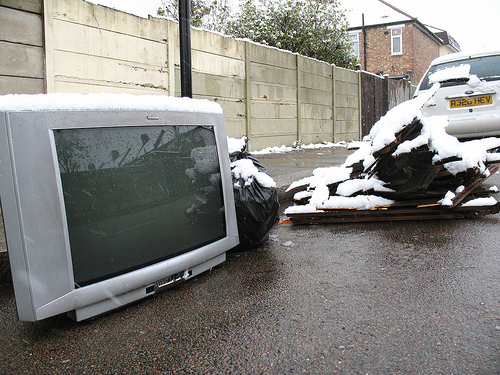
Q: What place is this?
A: It is a pavement.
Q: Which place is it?
A: It is a pavement.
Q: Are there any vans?
A: No, there are no vans.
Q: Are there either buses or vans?
A: No, there are no vans or buses.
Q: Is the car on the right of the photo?
A: Yes, the car is on the right of the image.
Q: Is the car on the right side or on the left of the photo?
A: The car is on the right of the image.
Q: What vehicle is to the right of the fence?
A: The vehicle is a car.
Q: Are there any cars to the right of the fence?
A: Yes, there is a car to the right of the fence.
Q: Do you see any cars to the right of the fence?
A: Yes, there is a car to the right of the fence.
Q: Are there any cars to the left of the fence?
A: No, the car is to the right of the fence.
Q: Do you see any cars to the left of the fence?
A: No, the car is to the right of the fence.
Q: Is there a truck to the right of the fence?
A: No, there is a car to the right of the fence.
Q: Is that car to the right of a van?
A: No, the car is to the right of the fence.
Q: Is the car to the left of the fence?
A: No, the car is to the right of the fence.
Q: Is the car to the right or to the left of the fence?
A: The car is to the right of the fence.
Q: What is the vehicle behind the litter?
A: The vehicle is a car.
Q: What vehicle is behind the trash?
A: The vehicle is a car.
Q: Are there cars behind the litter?
A: Yes, there is a car behind the litter.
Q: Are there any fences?
A: Yes, there is a fence.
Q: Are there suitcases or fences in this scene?
A: Yes, there is a fence.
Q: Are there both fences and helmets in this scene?
A: No, there is a fence but no helmets.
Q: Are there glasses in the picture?
A: No, there are no glasses.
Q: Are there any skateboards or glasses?
A: No, there are no glasses or skateboards.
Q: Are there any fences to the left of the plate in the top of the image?
A: Yes, there is a fence to the left of the plate.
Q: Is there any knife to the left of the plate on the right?
A: No, there is a fence to the left of the plate.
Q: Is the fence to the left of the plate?
A: Yes, the fence is to the left of the plate.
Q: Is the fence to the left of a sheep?
A: No, the fence is to the left of the plate.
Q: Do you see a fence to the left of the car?
A: Yes, there is a fence to the left of the car.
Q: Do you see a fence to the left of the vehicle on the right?
A: Yes, there is a fence to the left of the car.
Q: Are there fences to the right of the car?
A: No, the fence is to the left of the car.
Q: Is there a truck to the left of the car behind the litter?
A: No, there is a fence to the left of the car.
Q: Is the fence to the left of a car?
A: Yes, the fence is to the left of a car.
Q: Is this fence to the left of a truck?
A: No, the fence is to the left of a car.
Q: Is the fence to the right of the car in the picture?
A: No, the fence is to the left of the car.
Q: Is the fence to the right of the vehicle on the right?
A: No, the fence is to the left of the car.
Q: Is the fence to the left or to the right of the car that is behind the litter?
A: The fence is to the left of the car.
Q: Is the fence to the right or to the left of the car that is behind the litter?
A: The fence is to the left of the car.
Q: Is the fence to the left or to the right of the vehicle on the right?
A: The fence is to the left of the car.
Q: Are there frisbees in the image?
A: No, there are no frisbees.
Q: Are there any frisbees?
A: No, there are no frisbees.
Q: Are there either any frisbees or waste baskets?
A: No, there are no frisbees or waste baskets.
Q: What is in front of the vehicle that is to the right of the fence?
A: The litter is in front of the car.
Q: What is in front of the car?
A: The litter is in front of the car.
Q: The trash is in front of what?
A: The trash is in front of the car.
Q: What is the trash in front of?
A: The trash is in front of the car.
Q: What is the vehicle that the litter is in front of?
A: The vehicle is a car.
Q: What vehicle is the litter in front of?
A: The litter is in front of the car.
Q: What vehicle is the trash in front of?
A: The litter is in front of the car.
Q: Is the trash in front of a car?
A: Yes, the trash is in front of a car.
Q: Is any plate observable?
A: Yes, there is a plate.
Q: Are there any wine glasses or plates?
A: Yes, there is a plate.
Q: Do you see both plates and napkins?
A: No, there is a plate but no napkins.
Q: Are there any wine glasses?
A: No, there are no wine glasses.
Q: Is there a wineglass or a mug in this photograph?
A: No, there are no wine glasses or mugs.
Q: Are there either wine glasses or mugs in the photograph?
A: No, there are no wine glasses or mugs.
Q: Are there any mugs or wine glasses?
A: No, there are no wine glasses or mugs.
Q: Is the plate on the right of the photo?
A: Yes, the plate is on the right of the image.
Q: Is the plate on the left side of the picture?
A: No, the plate is on the right of the image.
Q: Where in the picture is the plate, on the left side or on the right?
A: The plate is on the right of the image.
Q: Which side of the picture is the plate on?
A: The plate is on the right of the image.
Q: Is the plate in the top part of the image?
A: Yes, the plate is in the top of the image.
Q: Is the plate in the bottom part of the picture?
A: No, the plate is in the top of the image.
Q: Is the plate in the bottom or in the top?
A: The plate is in the top of the image.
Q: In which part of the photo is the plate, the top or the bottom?
A: The plate is in the top of the image.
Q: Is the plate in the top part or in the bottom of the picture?
A: The plate is in the top of the image.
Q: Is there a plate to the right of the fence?
A: Yes, there is a plate to the right of the fence.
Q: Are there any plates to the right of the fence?
A: Yes, there is a plate to the right of the fence.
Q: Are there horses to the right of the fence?
A: No, there is a plate to the right of the fence.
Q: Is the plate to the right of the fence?
A: Yes, the plate is to the right of the fence.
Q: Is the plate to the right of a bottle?
A: No, the plate is to the right of the fence.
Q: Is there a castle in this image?
A: No, there are no castles.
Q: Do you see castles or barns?
A: No, there are no castles or barns.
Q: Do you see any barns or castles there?
A: No, there are no castles or barns.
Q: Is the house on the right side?
A: Yes, the house is on the right of the image.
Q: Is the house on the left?
A: No, the house is on the right of the image.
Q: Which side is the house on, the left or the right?
A: The house is on the right of the image.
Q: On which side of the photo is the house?
A: The house is on the right of the image.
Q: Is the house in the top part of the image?
A: Yes, the house is in the top of the image.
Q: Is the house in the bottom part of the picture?
A: No, the house is in the top of the image.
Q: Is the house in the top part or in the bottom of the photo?
A: The house is in the top of the image.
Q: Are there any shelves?
A: No, there are no shelves.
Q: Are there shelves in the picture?
A: No, there are no shelves.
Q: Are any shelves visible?
A: No, there are no shelves.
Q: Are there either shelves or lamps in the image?
A: No, there are no shelves or lamps.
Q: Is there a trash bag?
A: Yes, there is a trash bag.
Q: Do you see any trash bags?
A: Yes, there is a trash bag.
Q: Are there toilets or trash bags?
A: Yes, there is a trash bag.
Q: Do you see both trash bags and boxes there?
A: Yes, there are both a trash bag and a box.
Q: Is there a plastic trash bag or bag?
A: Yes, there is a plastic trash bag.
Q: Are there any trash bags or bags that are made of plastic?
A: Yes, the trash bag is made of plastic.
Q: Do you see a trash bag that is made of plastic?
A: Yes, there is a trash bag that is made of plastic.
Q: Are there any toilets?
A: No, there are no toilets.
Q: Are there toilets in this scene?
A: No, there are no toilets.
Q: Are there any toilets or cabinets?
A: No, there are no toilets or cabinets.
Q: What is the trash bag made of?
A: The trash bag is made of plastic.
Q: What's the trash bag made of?
A: The trash bag is made of plastic.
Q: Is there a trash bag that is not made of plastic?
A: No, there is a trash bag but it is made of plastic.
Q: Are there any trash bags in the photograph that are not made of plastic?
A: No, there is a trash bag but it is made of plastic.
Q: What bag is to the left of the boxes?
A: The bag is a trash bag.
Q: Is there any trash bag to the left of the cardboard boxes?
A: Yes, there is a trash bag to the left of the boxes.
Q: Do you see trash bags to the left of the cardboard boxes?
A: Yes, there is a trash bag to the left of the boxes.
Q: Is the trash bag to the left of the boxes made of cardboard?
A: Yes, the trash bag is to the left of the boxes.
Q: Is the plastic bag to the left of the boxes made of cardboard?
A: Yes, the trash bag is to the left of the boxes.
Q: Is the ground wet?
A: Yes, the ground is wet.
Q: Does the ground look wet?
A: Yes, the ground is wet.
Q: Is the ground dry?
A: No, the ground is wet.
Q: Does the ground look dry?
A: No, the ground is wet.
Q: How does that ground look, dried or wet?
A: The ground is wet.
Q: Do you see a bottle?
A: No, there are no bottles.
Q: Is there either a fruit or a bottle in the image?
A: No, there are no bottles or fruits.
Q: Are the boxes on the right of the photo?
A: Yes, the boxes are on the right of the image.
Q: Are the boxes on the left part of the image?
A: No, the boxes are on the right of the image.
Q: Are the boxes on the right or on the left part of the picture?
A: The boxes are on the right of the image.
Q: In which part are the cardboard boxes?
A: The boxes are on the right of the image.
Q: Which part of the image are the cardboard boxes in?
A: The boxes are on the right of the image.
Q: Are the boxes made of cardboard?
A: Yes, the boxes are made of cardboard.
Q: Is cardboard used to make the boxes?
A: Yes, the boxes are made of cardboard.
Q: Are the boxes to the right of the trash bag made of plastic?
A: No, the boxes are made of cardboard.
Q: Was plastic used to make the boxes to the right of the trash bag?
A: No, the boxes are made of cardboard.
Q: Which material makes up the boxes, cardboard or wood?
A: The boxes are made of cardboard.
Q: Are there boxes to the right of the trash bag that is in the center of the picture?
A: Yes, there are boxes to the right of the trash bag.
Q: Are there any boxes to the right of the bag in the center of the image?
A: Yes, there are boxes to the right of the trash bag.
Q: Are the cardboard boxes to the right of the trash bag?
A: Yes, the boxes are to the right of the trash bag.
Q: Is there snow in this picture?
A: Yes, there is snow.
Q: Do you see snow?
A: Yes, there is snow.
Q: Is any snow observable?
A: Yes, there is snow.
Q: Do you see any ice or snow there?
A: Yes, there is snow.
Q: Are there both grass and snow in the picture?
A: No, there is snow but no grass.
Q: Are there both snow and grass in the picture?
A: No, there is snow but no grass.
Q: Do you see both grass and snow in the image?
A: No, there is snow but no grass.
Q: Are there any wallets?
A: No, there are no wallets.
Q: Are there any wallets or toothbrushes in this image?
A: No, there are no wallets or toothbrushes.